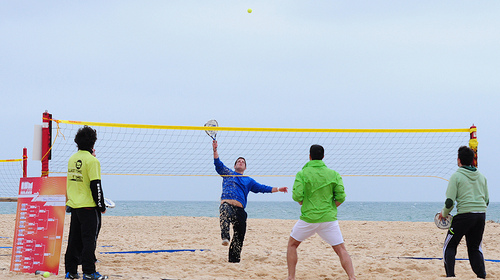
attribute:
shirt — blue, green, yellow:
[216, 159, 255, 206]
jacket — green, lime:
[291, 163, 348, 218]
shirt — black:
[89, 175, 106, 217]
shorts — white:
[291, 219, 349, 246]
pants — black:
[450, 209, 483, 255]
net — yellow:
[180, 118, 290, 138]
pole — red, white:
[36, 112, 59, 173]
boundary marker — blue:
[114, 241, 215, 262]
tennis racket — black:
[199, 115, 222, 141]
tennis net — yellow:
[137, 122, 186, 161]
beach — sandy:
[136, 224, 172, 244]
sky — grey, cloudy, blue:
[213, 23, 313, 53]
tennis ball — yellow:
[241, 3, 258, 23]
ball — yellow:
[245, 7, 261, 25]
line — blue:
[388, 248, 442, 267]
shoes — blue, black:
[64, 271, 103, 279]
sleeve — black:
[91, 178, 104, 203]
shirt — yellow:
[68, 162, 92, 207]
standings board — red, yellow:
[17, 172, 67, 204]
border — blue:
[375, 219, 400, 222]